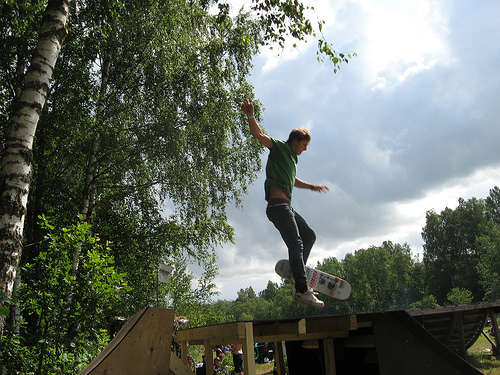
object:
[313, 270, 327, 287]
stickers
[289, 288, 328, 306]
shoes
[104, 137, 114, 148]
leaves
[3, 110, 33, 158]
moss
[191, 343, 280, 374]
people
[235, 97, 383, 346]
he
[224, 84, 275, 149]
arm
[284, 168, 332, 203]
arm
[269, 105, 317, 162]
head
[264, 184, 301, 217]
belt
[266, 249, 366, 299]
skateboard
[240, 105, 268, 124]
watch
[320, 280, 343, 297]
wheels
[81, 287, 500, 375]
ramp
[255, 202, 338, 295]
jeans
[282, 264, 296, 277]
wheels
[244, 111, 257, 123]
watch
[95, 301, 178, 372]
skateboard ramp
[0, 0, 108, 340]
trees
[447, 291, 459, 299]
leaves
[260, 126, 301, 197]
shirt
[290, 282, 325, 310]
sport shoe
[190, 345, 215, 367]
spectator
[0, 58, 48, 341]
tree trunk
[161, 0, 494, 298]
sky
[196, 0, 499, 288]
clouds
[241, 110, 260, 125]
person's wrist